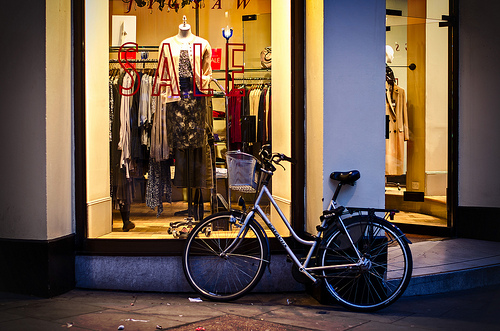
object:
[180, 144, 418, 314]
bicycle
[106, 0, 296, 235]
window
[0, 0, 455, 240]
store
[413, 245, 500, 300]
step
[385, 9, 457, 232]
door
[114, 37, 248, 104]
sale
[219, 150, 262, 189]
basket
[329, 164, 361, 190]
seat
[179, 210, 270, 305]
wheel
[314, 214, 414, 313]
wheel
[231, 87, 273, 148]
clothing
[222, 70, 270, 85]
rack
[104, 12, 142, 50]
vase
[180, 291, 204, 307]
trash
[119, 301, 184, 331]
ground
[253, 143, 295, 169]
handlebars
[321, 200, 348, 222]
rack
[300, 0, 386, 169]
wall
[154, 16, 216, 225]
mannequin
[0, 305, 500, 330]
pavement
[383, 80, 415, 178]
coat